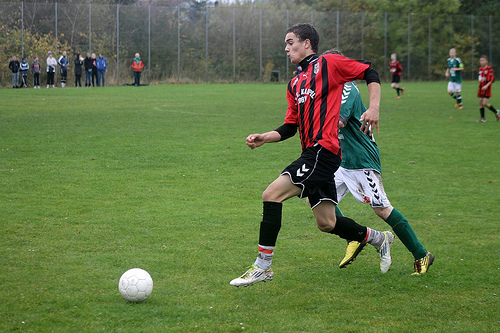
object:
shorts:
[281, 146, 343, 209]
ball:
[117, 266, 156, 301]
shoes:
[412, 253, 433, 276]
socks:
[260, 202, 283, 254]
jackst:
[128, 60, 148, 72]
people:
[94, 54, 107, 90]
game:
[50, 51, 498, 329]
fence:
[0, 0, 497, 84]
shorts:
[324, 166, 392, 210]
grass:
[0, 80, 500, 333]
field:
[0, 81, 500, 332]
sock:
[327, 218, 370, 247]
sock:
[382, 207, 431, 256]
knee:
[376, 208, 389, 222]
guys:
[227, 24, 394, 288]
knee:
[258, 188, 281, 209]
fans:
[127, 51, 143, 86]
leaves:
[375, 15, 386, 21]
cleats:
[426, 252, 433, 273]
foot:
[412, 249, 432, 284]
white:
[294, 169, 313, 175]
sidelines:
[119, 77, 263, 87]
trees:
[0, 0, 499, 84]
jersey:
[271, 51, 380, 159]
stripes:
[321, 61, 329, 146]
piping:
[300, 150, 320, 184]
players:
[318, 48, 436, 279]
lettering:
[294, 89, 317, 109]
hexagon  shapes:
[134, 278, 148, 292]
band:
[255, 244, 277, 256]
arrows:
[372, 192, 383, 199]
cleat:
[341, 245, 362, 268]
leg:
[258, 162, 306, 261]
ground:
[0, 87, 500, 333]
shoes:
[225, 266, 273, 287]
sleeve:
[357, 63, 380, 84]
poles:
[175, 14, 183, 85]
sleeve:
[326, 51, 368, 83]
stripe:
[354, 119, 380, 155]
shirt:
[333, 79, 381, 172]